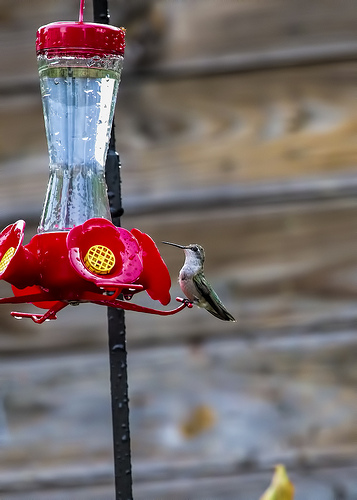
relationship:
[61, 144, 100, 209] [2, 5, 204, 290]
water in feeder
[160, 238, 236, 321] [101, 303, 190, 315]
bird on perch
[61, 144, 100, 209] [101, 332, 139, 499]
water on pole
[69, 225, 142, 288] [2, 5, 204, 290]
shape on feeder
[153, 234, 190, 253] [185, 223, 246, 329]
beak on bird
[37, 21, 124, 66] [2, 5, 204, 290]
cap on feeder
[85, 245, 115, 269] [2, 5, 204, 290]
middle on feeder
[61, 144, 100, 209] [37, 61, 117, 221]
water on glass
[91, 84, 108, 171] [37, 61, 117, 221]
reflection on glass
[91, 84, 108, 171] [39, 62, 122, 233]
reflection on plastic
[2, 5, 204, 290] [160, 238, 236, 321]
feeder of bird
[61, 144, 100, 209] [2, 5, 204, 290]
water on feeder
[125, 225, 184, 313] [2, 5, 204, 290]
feeding station on feeder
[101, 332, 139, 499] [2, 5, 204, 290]
pole supporting feeder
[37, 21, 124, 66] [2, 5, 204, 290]
cap of feeder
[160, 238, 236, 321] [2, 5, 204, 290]
bird sitting on feeder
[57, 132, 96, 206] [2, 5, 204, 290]
food in feeder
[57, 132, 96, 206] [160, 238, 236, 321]
food of bird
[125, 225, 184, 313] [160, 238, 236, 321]
feeding station of bird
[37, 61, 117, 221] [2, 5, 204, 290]
glass of feeder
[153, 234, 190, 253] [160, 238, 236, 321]
beak of bird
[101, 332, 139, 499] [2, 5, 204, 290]
pole holding up feeder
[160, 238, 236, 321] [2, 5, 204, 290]
bird on side of feeder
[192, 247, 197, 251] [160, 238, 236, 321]
eye of bird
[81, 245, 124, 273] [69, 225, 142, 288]
middle of flower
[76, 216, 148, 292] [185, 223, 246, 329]
flower left of bird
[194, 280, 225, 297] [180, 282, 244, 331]
wings on body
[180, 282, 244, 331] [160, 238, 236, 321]
body of bird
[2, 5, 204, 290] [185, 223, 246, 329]
feeder of bird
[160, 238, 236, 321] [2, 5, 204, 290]
bird on feeder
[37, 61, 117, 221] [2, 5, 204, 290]
glass on feeder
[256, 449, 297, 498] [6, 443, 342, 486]
bird on ground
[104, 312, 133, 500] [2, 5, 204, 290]
pole of feeder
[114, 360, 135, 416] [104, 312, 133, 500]
water on pole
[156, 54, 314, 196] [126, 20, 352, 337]
wall in background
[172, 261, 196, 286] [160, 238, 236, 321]
feathers on bird